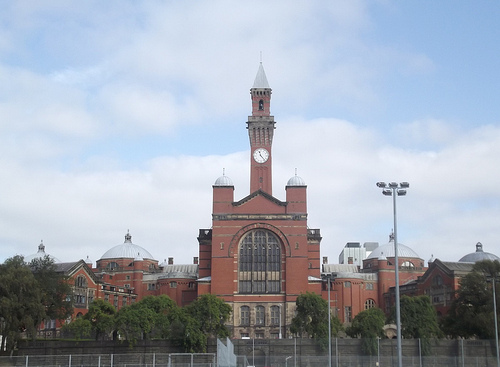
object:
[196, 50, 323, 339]
building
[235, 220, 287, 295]
window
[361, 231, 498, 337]
buildings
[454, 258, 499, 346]
trees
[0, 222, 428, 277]
front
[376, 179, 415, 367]
light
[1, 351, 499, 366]
fence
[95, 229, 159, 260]
dome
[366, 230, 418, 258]
domes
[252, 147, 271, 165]
clock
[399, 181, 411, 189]
lights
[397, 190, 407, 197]
lights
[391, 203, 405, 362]
pole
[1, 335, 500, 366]
foreground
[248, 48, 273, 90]
top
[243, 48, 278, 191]
tower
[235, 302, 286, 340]
three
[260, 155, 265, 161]
hands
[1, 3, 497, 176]
sky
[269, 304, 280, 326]
windows